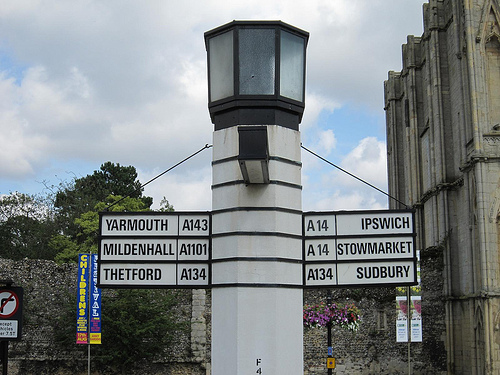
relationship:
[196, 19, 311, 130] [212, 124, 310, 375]
light on post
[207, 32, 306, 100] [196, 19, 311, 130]
panes are around light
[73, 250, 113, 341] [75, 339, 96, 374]
banner on a pole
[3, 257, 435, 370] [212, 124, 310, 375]
wall behind post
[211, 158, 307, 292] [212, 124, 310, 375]
stripes are around post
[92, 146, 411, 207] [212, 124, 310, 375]
cable connected to post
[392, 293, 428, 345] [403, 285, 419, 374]
banner on a pole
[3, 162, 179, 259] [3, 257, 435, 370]
trees are behind wall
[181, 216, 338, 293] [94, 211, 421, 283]
numbers are on sign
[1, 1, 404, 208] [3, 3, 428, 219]
clouds are in sky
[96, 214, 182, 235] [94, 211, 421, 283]
yarmouth on sign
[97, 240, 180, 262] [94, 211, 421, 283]
mildenhall on sign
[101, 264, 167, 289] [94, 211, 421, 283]
thetford on sign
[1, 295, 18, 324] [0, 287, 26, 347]
no right on traffic sign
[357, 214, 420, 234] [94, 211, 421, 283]
ipswich on sign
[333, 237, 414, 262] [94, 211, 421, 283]
stowmarket on sign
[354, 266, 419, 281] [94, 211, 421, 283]
sudbury on sign